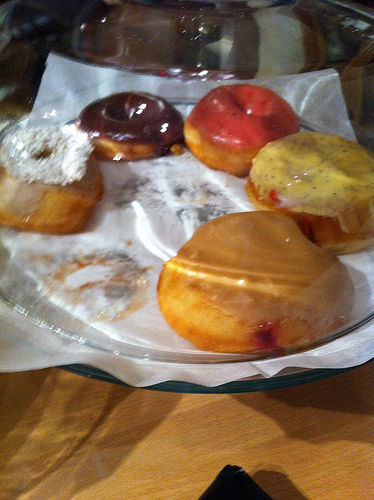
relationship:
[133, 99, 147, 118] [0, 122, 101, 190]
light on powdered sugar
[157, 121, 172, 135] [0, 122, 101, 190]
light on powdered sugar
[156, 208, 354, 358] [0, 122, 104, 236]
donut of piece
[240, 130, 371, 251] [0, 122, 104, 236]
piece of piece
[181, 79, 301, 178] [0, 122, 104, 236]
piece of piece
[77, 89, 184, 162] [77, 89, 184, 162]
piece of piece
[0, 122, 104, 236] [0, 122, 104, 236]
piece of piece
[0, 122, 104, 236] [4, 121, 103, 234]
piece of food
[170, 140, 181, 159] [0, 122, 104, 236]
piece of piece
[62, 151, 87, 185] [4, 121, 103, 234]
piece of food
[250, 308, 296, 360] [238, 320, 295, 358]
jelly filling coming out of hole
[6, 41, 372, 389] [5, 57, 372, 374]
paper under donuts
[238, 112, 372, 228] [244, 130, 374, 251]
icing on piece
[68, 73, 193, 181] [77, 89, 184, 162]
icing on piece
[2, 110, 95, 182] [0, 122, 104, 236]
powdered sugar on top of piece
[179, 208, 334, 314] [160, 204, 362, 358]
caramel icing on top of donut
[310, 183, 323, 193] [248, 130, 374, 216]
dark speck in icing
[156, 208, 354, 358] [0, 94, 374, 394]
donut under serving plate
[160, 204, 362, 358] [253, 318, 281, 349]
donut with jelly filling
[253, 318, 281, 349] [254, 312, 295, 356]
jelly filling escaping from hole